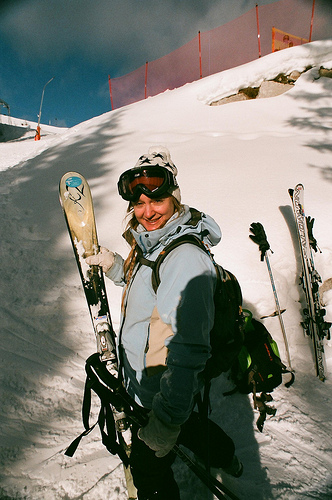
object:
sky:
[1, 1, 332, 128]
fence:
[107, 1, 330, 115]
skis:
[60, 170, 145, 499]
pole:
[287, 183, 327, 384]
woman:
[86, 149, 220, 500]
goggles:
[118, 166, 175, 202]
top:
[106, 205, 222, 432]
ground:
[1, 40, 331, 500]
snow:
[1, 39, 332, 500]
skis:
[286, 183, 326, 381]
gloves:
[249, 223, 275, 261]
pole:
[263, 240, 294, 374]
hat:
[121, 146, 181, 193]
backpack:
[135, 234, 243, 386]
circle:
[66, 176, 83, 190]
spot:
[70, 374, 76, 382]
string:
[135, 255, 158, 269]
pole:
[107, 77, 117, 112]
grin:
[141, 214, 162, 224]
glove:
[138, 412, 182, 459]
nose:
[144, 204, 155, 220]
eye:
[151, 197, 163, 204]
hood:
[188, 207, 224, 249]